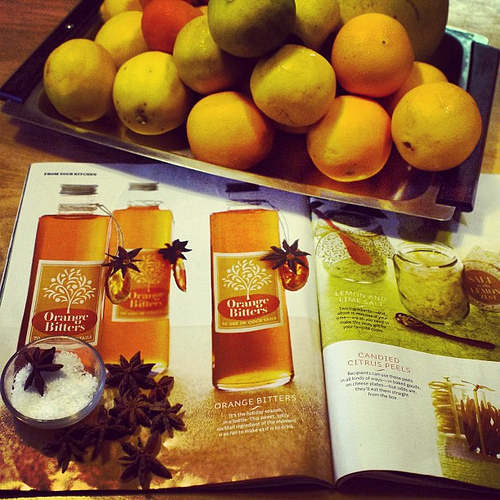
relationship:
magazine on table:
[3, 159, 499, 498] [2, 3, 499, 499]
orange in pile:
[188, 91, 275, 172] [42, 2, 484, 186]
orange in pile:
[329, 12, 415, 100] [42, 2, 484, 186]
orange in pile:
[389, 77, 484, 172] [42, 2, 484, 186]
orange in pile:
[304, 93, 396, 186] [42, 2, 484, 186]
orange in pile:
[388, 59, 450, 124] [42, 2, 484, 186]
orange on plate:
[188, 91, 275, 172] [4, 2, 499, 225]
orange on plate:
[389, 77, 484, 172] [4, 2, 499, 225]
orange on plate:
[329, 12, 415, 100] [4, 2, 499, 225]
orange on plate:
[388, 59, 450, 124] [4, 2, 499, 225]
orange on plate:
[304, 93, 396, 186] [4, 2, 499, 225]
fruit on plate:
[43, 0, 486, 188] [4, 2, 499, 225]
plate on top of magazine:
[4, 2, 499, 225] [3, 159, 499, 498]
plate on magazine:
[4, 2, 499, 225] [3, 159, 499, 498]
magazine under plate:
[3, 159, 499, 498] [4, 2, 499, 225]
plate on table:
[4, 2, 499, 225] [2, 3, 499, 499]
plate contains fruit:
[4, 2, 499, 225] [43, 0, 486, 188]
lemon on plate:
[111, 45, 192, 137] [4, 2, 499, 225]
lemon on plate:
[97, 10, 150, 65] [4, 2, 499, 225]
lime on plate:
[204, 3, 297, 60] [4, 2, 499, 225]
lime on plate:
[171, 13, 245, 97] [4, 2, 499, 225]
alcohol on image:
[206, 177, 299, 395] [14, 160, 317, 472]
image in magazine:
[14, 160, 317, 472] [3, 159, 499, 498]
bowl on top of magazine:
[2, 330, 114, 438] [3, 159, 499, 498]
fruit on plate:
[41, 38, 117, 124] [4, 2, 499, 225]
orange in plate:
[304, 93, 396, 186] [4, 2, 499, 225]